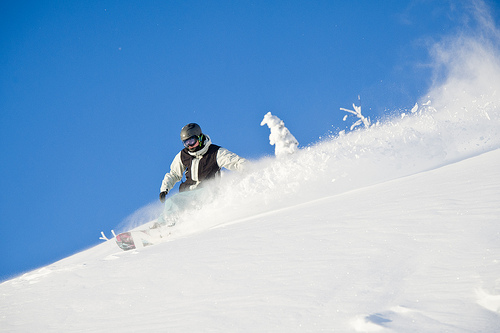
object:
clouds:
[86, 52, 211, 117]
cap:
[179, 122, 202, 141]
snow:
[247, 209, 495, 327]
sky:
[0, 0, 500, 330]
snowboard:
[116, 217, 176, 251]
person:
[159, 122, 253, 227]